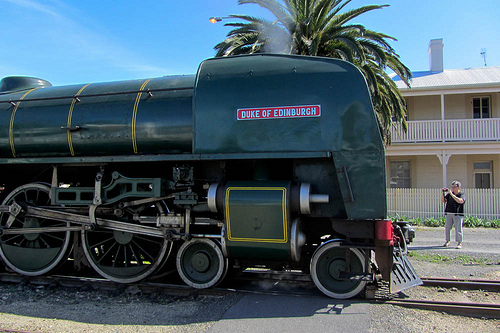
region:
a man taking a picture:
[414, 165, 483, 248]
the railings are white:
[389, 106, 498, 148]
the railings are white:
[381, 170, 463, 243]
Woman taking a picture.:
[425, 175, 472, 249]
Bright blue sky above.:
[130, 13, 192, 53]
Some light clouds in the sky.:
[35, 11, 136, 63]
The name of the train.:
[232, 97, 326, 131]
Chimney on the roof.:
[426, 29, 451, 81]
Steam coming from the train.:
[240, 4, 307, 58]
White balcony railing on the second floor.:
[400, 115, 493, 145]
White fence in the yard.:
[386, 184, 439, 211]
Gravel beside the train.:
[17, 295, 179, 328]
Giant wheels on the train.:
[0, 180, 169, 285]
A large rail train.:
[7, 8, 483, 309]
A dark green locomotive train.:
[0, 62, 407, 297]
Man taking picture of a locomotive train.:
[288, 26, 482, 306]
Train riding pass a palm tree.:
[218, 3, 405, 319]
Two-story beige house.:
[338, 28, 492, 248]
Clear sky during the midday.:
[10, 6, 493, 128]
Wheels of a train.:
[0, 157, 380, 297]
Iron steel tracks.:
[308, 200, 487, 318]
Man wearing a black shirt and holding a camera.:
[436, 174, 472, 249]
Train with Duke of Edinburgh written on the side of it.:
[225, 94, 332, 134]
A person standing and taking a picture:
[435, 181, 465, 248]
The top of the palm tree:
[221, 5, 402, 60]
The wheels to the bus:
[10, 186, 217, 283]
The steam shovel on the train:
[372, 245, 422, 295]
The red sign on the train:
[241, 108, 325, 119]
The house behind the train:
[390, 78, 497, 216]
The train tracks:
[387, 265, 492, 307]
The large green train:
[17, 51, 401, 298]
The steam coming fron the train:
[257, 6, 297, 58]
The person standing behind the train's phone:
[441, 189, 446, 190]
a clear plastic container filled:
[3, 188, 69, 275]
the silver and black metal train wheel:
[77, 183, 169, 278]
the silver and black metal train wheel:
[177, 233, 227, 284]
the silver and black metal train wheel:
[310, 233, 365, 296]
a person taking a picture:
[439, 177, 467, 241]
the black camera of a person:
[440, 186, 448, 194]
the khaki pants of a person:
[444, 213, 463, 240]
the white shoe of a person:
[438, 237, 451, 247]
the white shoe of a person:
[453, 241, 460, 247]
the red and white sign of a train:
[237, 105, 319, 120]